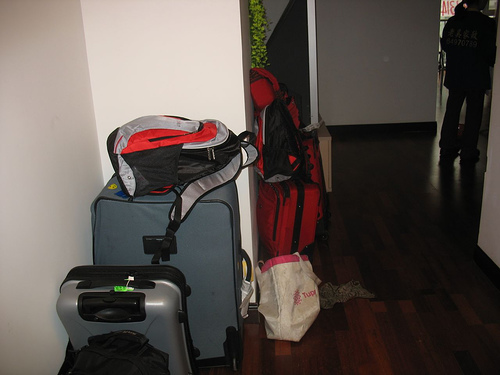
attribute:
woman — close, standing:
[426, 1, 497, 162]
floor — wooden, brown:
[87, 123, 500, 372]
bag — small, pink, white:
[250, 240, 330, 361]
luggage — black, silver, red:
[56, 95, 249, 374]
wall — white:
[0, 4, 259, 371]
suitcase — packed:
[57, 261, 196, 373]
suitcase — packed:
[91, 173, 243, 366]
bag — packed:
[252, 253, 324, 342]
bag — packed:
[63, 326, 172, 372]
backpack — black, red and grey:
[96, 106, 259, 229]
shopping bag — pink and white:
[250, 246, 323, 342]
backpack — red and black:
[255, 95, 310, 185]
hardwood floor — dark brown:
[340, 143, 466, 370]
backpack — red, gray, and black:
[103, 116, 263, 199]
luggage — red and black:
[258, 177, 320, 250]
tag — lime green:
[113, 283, 133, 298]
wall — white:
[0, 3, 82, 183]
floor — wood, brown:
[338, 159, 476, 372]